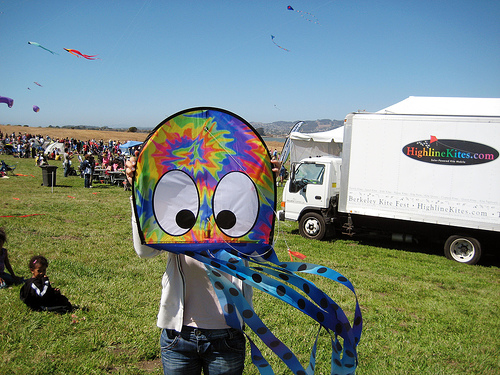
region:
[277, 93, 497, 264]
white truck with rainbow-colored logo on side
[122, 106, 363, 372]
person holding multi-colored kite in front of face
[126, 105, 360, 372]
multi-colored kite with big eyes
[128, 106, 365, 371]
kite with blue and black polka-dotted streamers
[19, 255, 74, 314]
little girl dressed in black and white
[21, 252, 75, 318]
little girl sitting on the ground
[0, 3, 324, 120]
blue sky filled with many kites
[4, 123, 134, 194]
crowd of people in distance watching and flying kites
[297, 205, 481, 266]
two tires on a white truck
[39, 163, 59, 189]
black garbage can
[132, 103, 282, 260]
Coloeful funny large kite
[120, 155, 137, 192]
Hand of kite holder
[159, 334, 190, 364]
Part of jeans of kite holder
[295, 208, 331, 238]
Front tire of truck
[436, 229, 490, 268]
Back tire of truck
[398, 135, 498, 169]
Advertising sign on white truck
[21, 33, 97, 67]
Two kites flying aloft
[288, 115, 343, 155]
White spectator shelter tent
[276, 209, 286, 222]
Front bumper of white truck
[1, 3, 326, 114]
Kites are flying through the air.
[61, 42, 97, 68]
The kite is red.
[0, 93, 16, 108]
The kite is purple.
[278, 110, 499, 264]
The truck is white.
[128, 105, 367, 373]
The kite is rainbow colored.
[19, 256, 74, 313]
A child sits in the grass.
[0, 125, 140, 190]
A crowd of people are watching kites.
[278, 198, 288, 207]
The light is orange.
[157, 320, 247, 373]
The person is wearing jeans.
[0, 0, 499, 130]
The sky is clear and blue.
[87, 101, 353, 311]
Multi-colored kite with big eyes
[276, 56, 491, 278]
Truck with kite company logo on it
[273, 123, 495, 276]
Truck parked on grass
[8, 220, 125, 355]
Little girl sitting on grass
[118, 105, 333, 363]
Woman holding up a kite with big eyes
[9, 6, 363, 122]
A few kites in the air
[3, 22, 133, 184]
Large group gathered together watching kites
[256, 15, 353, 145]
Blue sky and mountain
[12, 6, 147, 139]
Brown field and blue skies and kite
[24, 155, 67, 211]
Trashcan sitting on grass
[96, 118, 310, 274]
Kite with eye balls on it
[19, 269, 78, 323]
child in all black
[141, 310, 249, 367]
person wearing blue jeans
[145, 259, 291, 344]
woman wearing white shirt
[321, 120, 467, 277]
white box truck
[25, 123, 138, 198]
crowd standing around an event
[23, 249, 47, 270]
child with bow in hair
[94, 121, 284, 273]
rainbow kite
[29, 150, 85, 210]
garbage can in the event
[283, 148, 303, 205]
mirror on a box truck